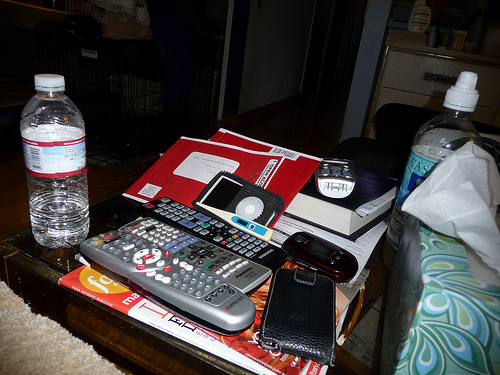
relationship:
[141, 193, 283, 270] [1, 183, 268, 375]
remote on table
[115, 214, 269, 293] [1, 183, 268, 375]
remote on table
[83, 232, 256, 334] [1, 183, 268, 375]
remote on table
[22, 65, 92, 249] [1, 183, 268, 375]
water bottle on table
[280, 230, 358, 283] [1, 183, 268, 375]
cellphone on table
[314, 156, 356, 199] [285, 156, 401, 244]
remote on book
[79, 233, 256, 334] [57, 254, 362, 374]
remote on magazine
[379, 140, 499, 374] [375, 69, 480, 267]
tissue box next to bottle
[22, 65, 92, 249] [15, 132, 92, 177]
water bottle has label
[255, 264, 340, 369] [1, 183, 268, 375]
wallet on table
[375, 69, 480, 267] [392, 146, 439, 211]
bottle with label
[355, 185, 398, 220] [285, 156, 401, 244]
paper inside book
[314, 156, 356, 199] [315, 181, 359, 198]
remote with edges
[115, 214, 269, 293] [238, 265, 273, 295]
remote with sharp edge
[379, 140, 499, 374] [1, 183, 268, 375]
tissue box on table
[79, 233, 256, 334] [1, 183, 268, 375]
remote on table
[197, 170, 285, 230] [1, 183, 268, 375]
ipod on table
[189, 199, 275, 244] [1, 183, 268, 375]
thermometer on table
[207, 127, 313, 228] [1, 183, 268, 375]
mail on table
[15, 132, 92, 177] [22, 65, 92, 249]
label on water bottle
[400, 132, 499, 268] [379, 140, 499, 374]
tissues sticking out of tissue box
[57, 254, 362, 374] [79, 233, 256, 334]
magazine under remote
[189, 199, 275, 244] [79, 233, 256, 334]
thermometer by remote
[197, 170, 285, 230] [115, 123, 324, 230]
ipod on letters